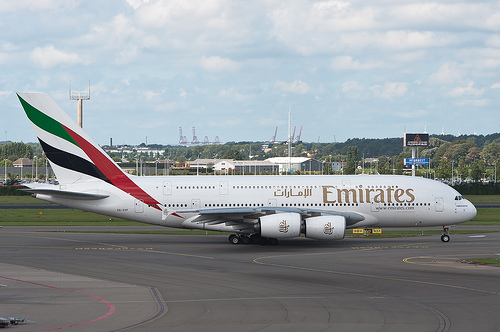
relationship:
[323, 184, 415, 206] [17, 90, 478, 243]
name on plane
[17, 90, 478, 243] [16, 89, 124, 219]
plane has a tail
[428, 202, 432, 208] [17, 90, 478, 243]
window on plane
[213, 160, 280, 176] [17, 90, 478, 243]
building behind plane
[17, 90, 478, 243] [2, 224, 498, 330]
plane on runway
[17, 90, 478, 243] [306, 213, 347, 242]
plane has an engine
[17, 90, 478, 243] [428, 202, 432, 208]
airplane has a window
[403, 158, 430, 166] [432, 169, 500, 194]
sign in parking lot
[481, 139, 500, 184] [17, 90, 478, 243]
tree by plane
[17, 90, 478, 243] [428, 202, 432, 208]
plane has a window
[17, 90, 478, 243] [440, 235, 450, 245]
plane has a wheel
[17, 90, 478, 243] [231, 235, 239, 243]
plane has a back wheel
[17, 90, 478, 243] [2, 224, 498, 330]
plane on ground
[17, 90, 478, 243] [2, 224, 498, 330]
airplane on ground